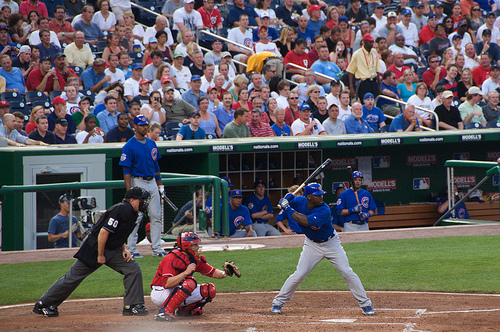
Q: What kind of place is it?
A: It is a field.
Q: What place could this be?
A: It is a field.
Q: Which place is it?
A: It is a field.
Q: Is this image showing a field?
A: Yes, it is showing a field.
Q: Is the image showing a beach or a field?
A: It is showing a field.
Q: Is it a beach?
A: No, it is a field.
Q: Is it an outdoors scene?
A: Yes, it is outdoors.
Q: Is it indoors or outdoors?
A: It is outdoors.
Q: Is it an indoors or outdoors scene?
A: It is outdoors.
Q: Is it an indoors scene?
A: No, it is outdoors.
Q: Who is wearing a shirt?
A: The man is wearing a shirt.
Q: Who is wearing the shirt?
A: The man is wearing a shirt.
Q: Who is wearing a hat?
A: The man is wearing a hat.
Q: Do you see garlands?
A: No, there are no garlands.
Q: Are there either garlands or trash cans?
A: No, there are no garlands or trash cans.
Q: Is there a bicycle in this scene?
A: No, there are no bicycles.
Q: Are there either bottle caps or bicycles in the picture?
A: No, there are no bicycles or bottle caps.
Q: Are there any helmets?
A: Yes, there is a helmet.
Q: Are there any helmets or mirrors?
A: Yes, there is a helmet.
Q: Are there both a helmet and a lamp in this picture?
A: No, there is a helmet but no lamps.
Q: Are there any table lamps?
A: No, there are no table lamps.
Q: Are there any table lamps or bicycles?
A: No, there are no table lamps or bicycles.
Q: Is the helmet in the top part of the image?
A: No, the helmet is in the bottom of the image.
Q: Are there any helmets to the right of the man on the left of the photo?
A: Yes, there is a helmet to the right of the man.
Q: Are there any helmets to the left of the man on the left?
A: No, the helmet is to the right of the man.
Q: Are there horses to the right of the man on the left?
A: No, there is a helmet to the right of the man.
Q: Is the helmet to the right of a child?
A: No, the helmet is to the right of the man.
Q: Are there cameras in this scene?
A: Yes, there is a camera.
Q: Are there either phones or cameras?
A: Yes, there is a camera.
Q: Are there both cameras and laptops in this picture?
A: No, there is a camera but no laptops.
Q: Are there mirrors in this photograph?
A: No, there are no mirrors.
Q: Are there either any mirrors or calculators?
A: No, there are no mirrors or calculators.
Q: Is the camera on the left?
A: Yes, the camera is on the left of the image.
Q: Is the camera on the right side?
A: No, the camera is on the left of the image.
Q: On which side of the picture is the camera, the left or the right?
A: The camera is on the left of the image.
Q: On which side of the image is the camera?
A: The camera is on the left of the image.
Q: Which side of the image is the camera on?
A: The camera is on the left of the image.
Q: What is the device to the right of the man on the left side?
A: The device is a camera.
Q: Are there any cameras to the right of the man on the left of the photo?
A: Yes, there is a camera to the right of the man.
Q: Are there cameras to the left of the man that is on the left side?
A: No, the camera is to the right of the man.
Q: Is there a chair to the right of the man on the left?
A: No, there is a camera to the right of the man.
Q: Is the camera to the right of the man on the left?
A: Yes, the camera is to the right of the man.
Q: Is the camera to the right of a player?
A: No, the camera is to the right of the man.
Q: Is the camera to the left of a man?
A: No, the camera is to the right of a man.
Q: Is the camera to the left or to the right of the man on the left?
A: The camera is to the right of the man.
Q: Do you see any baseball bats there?
A: Yes, there is a baseball bat.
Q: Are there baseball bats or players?
A: Yes, there is a baseball bat.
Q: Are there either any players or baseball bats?
A: Yes, there is a baseball bat.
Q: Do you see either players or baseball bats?
A: Yes, there is a baseball bat.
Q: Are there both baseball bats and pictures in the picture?
A: No, there is a baseball bat but no pictures.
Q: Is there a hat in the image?
A: Yes, there is a hat.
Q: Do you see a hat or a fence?
A: Yes, there is a hat.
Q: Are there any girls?
A: No, there are no girls.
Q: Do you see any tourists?
A: No, there are no tourists.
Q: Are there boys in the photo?
A: No, there are no boys.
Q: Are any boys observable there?
A: No, there are no boys.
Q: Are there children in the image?
A: No, there are no children.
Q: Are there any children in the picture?
A: No, there are no children.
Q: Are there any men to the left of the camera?
A: Yes, there is a man to the left of the camera.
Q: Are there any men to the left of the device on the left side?
A: Yes, there is a man to the left of the camera.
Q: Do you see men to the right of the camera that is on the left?
A: No, the man is to the left of the camera.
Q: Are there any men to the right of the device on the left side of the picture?
A: No, the man is to the left of the camera.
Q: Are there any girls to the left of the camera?
A: No, there is a man to the left of the camera.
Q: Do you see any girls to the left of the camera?
A: No, there is a man to the left of the camera.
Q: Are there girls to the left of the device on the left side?
A: No, there is a man to the left of the camera.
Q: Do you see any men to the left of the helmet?
A: Yes, there is a man to the left of the helmet.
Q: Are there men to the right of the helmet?
A: No, the man is to the left of the helmet.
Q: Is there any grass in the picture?
A: Yes, there is grass.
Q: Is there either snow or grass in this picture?
A: Yes, there is grass.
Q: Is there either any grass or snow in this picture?
A: Yes, there is grass.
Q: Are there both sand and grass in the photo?
A: No, there is grass but no sand.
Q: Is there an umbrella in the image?
A: No, there are no umbrellas.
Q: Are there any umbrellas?
A: No, there are no umbrellas.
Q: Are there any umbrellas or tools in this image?
A: No, there are no umbrellas or tools.